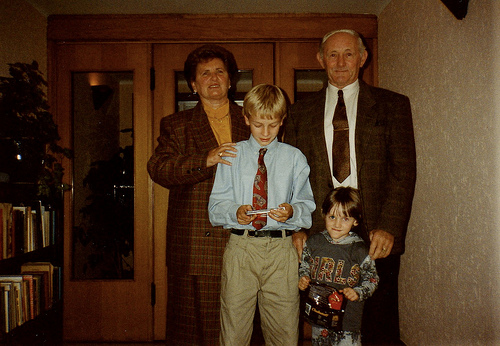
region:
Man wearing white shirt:
[320, 77, 370, 192]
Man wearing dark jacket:
[276, 74, 451, 252]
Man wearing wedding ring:
[374, 239, 392, 257]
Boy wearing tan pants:
[214, 216, 309, 342]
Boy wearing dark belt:
[223, 219, 301, 244]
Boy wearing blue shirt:
[206, 133, 322, 245]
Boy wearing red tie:
[230, 129, 283, 237]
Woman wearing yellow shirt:
[189, 97, 250, 163]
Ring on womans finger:
[211, 146, 229, 163]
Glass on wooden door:
[56, 57, 149, 294]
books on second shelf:
[6, 270, 71, 326]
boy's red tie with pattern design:
[248, 141, 278, 231]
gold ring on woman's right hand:
[216, 146, 239, 163]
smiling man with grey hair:
[315, 30, 384, 96]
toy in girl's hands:
[304, 284, 371, 339]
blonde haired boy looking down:
[239, 77, 314, 157]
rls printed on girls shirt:
[321, 250, 361, 288]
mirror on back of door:
[61, 55, 159, 309]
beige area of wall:
[438, 52, 486, 176]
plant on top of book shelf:
[6, 62, 71, 196]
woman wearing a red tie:
[246, 145, 271, 237]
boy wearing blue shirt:
[215, 132, 321, 240]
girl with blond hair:
[323, 185, 363, 240]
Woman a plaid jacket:
[159, 99, 230, 209]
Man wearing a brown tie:
[315, 93, 355, 152]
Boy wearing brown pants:
[214, 238, 311, 340]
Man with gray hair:
[317, 29, 364, 79]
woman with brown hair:
[169, 42, 250, 89]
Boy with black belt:
[233, 226, 319, 256]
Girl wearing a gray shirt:
[306, 235, 384, 317]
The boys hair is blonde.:
[236, 85, 291, 143]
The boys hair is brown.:
[321, 186, 358, 241]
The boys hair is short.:
[317, 183, 357, 237]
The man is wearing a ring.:
[360, 222, 397, 265]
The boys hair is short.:
[245, 80, 287, 145]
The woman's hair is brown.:
[184, 42, 240, 99]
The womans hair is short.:
[184, 44, 239, 103]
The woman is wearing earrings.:
[177, 38, 239, 102]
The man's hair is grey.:
[313, 29, 373, 85]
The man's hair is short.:
[316, 25, 373, 88]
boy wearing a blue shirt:
[218, 141, 298, 227]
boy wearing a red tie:
[248, 158, 265, 220]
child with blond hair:
[310, 188, 357, 226]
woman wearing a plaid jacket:
[147, 113, 227, 255]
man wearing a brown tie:
[315, 96, 352, 166]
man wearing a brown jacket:
[353, 82, 401, 204]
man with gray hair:
[310, 26, 377, 78]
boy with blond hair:
[240, 92, 282, 122]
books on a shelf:
[12, 246, 66, 317]